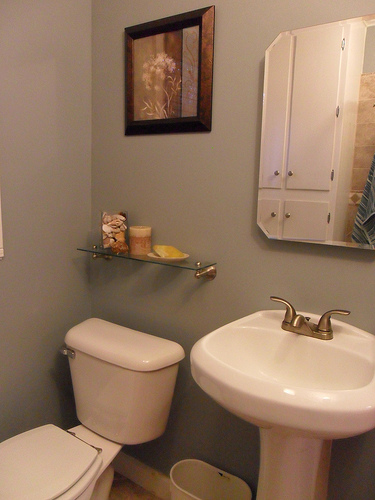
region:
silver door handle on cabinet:
[269, 158, 299, 183]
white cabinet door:
[277, 35, 336, 125]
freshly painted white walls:
[21, 150, 167, 180]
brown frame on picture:
[110, 7, 234, 149]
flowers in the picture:
[142, 53, 186, 107]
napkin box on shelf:
[85, 202, 133, 255]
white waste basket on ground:
[167, 453, 223, 488]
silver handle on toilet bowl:
[50, 339, 89, 362]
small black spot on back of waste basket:
[206, 465, 231, 480]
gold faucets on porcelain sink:
[256, 295, 361, 338]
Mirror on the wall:
[251, 24, 370, 265]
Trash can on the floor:
[155, 442, 257, 498]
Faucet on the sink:
[260, 275, 367, 338]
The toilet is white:
[40, 317, 194, 476]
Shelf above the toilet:
[73, 221, 243, 301]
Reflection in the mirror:
[311, 42, 371, 172]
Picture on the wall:
[108, 2, 224, 146]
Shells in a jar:
[91, 205, 133, 257]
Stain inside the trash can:
[201, 467, 236, 482]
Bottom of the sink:
[240, 381, 301, 493]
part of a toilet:
[67, 445, 77, 455]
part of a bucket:
[179, 480, 188, 486]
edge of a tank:
[134, 352, 136, 397]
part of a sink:
[271, 463, 284, 479]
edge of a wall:
[184, 393, 193, 409]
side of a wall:
[8, 354, 29, 383]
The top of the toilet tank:
[66, 315, 187, 371]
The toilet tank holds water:
[57, 341, 181, 447]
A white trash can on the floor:
[155, 445, 255, 496]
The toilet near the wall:
[1, 421, 112, 498]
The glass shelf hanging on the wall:
[74, 205, 218, 281]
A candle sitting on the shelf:
[127, 221, 152, 257]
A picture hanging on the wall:
[120, 3, 221, 137]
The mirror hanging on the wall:
[245, 14, 371, 252]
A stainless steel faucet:
[267, 294, 351, 341]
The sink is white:
[182, 309, 373, 468]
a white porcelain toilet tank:
[62, 315, 184, 447]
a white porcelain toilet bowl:
[0, 423, 124, 499]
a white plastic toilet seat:
[0, 424, 103, 499]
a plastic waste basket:
[168, 457, 253, 498]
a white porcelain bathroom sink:
[190, 306, 374, 498]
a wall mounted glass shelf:
[74, 240, 218, 283]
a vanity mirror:
[253, 11, 374, 251]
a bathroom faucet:
[268, 293, 348, 342]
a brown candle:
[126, 223, 151, 257]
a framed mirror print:
[122, 5, 214, 137]